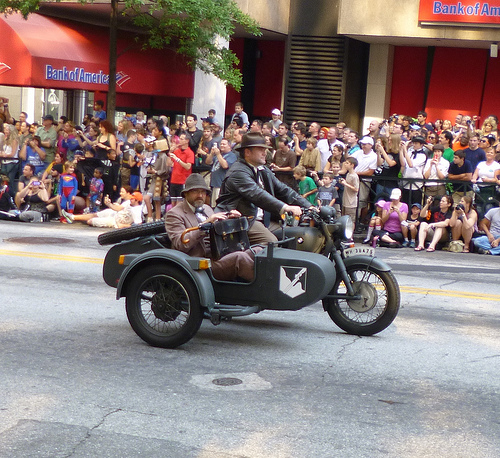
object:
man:
[215, 132, 319, 246]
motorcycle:
[97, 193, 400, 350]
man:
[164, 173, 262, 282]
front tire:
[324, 255, 400, 336]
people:
[3, 98, 222, 224]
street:
[3, 224, 90, 239]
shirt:
[253, 166, 264, 185]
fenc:
[360, 178, 500, 199]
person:
[372, 187, 410, 248]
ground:
[405, 254, 477, 298]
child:
[58, 162, 79, 215]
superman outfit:
[59, 174, 79, 215]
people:
[362, 188, 500, 257]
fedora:
[235, 131, 274, 151]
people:
[292, 109, 499, 252]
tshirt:
[381, 201, 409, 233]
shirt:
[423, 157, 451, 187]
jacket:
[215, 159, 313, 233]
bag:
[209, 216, 251, 260]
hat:
[398, 60, 496, 108]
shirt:
[447, 159, 472, 192]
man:
[62, 185, 134, 226]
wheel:
[97, 219, 171, 246]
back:
[97, 220, 165, 300]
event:
[0, 129, 489, 458]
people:
[73, 123, 99, 146]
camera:
[32, 120, 39, 125]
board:
[417, 0, 499, 28]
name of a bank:
[432, 1, 500, 18]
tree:
[14, 2, 263, 114]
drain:
[210, 376, 245, 386]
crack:
[83, 407, 127, 443]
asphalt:
[0, 350, 500, 451]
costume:
[87, 178, 104, 212]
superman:
[89, 177, 104, 211]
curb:
[396, 263, 500, 276]